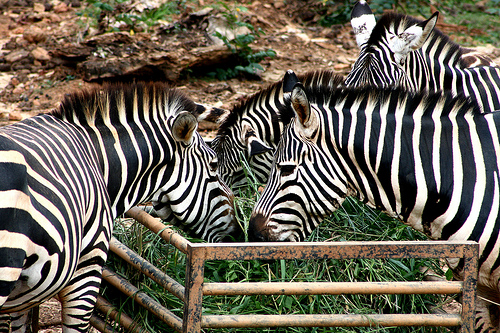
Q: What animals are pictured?
A: Zebra.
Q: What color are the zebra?
A: Black and white.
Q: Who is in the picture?
A: No one is in the picture.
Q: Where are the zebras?
A: At the zoo.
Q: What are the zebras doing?
A: Eating.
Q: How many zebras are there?
A: Four.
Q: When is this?
A: Daytime.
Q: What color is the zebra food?
A: Green.